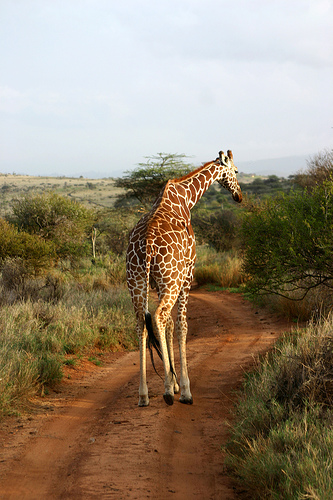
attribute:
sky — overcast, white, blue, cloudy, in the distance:
[0, 0, 332, 177]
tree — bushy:
[237, 197, 332, 295]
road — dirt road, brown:
[2, 291, 273, 498]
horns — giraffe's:
[213, 146, 239, 160]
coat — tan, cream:
[115, 164, 216, 334]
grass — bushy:
[10, 288, 112, 381]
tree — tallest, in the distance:
[8, 165, 113, 295]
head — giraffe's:
[213, 145, 248, 206]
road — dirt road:
[1, 289, 306, 498]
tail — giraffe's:
[138, 248, 163, 383]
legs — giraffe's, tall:
[132, 294, 197, 402]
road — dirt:
[39, 289, 286, 493]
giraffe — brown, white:
[123, 148, 244, 409]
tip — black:
[141, 310, 165, 377]